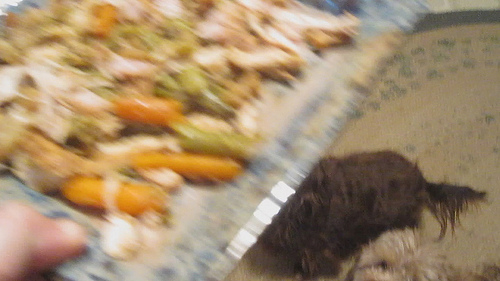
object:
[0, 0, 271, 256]
food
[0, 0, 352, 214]
chicken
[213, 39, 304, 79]
piece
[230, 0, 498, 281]
rug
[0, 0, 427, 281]
pan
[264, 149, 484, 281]
dog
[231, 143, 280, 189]
wall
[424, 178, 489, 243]
tail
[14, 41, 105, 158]
chunks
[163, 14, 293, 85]
chunks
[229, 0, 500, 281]
floor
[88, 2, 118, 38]
carrot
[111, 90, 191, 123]
carrot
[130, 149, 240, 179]
carrot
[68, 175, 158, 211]
carrot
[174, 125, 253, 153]
bean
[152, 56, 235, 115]
broccoli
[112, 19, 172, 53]
broccoli